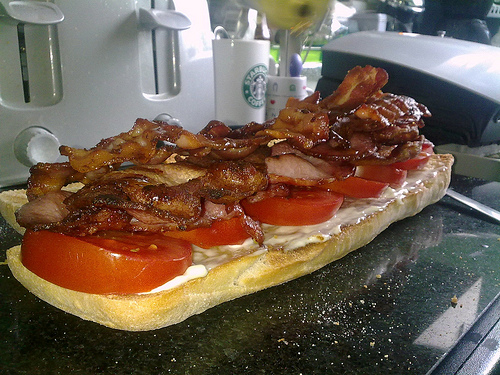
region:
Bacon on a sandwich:
[37, 138, 268, 238]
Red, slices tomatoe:
[17, 220, 221, 298]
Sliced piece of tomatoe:
[187, 210, 257, 239]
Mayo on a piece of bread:
[221, 213, 287, 256]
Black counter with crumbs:
[389, 230, 490, 295]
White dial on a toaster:
[13, 120, 77, 170]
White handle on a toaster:
[134, 9, 215, 108]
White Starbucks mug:
[217, 36, 290, 122]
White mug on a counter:
[270, 68, 337, 118]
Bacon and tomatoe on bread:
[251, 76, 496, 216]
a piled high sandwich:
[61, 78, 486, 308]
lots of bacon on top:
[55, 63, 469, 256]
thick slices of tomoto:
[66, 135, 420, 312]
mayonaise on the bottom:
[146, 160, 424, 287]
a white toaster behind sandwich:
[11, 0, 258, 178]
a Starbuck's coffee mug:
[211, 18, 289, 144]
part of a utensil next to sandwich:
[417, 165, 497, 225]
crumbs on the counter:
[297, 246, 474, 373]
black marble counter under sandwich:
[3, 176, 498, 366]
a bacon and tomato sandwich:
[25, 132, 439, 325]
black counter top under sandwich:
[1, 162, 496, 370]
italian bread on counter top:
[5, 150, 455, 335]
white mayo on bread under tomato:
[135, 260, 210, 295]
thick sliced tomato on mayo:
[15, 227, 190, 293]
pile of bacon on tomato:
[15, 65, 430, 245]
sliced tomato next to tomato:
[160, 215, 250, 247]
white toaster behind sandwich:
[0, 0, 212, 190]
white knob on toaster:
[11, 125, 58, 165]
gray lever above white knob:
[2, 0, 58, 21]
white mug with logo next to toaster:
[212, 35, 267, 121]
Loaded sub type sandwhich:
[6, 60, 454, 334]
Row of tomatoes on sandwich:
[21, 138, 438, 297]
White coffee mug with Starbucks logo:
[212, 36, 269, 125]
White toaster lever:
[131, 1, 193, 101]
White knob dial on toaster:
[11, 120, 61, 169]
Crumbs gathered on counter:
[313, 262, 498, 370]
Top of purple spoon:
[288, 50, 303, 77]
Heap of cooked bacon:
[15, 63, 432, 233]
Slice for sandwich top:
[0, 177, 83, 234]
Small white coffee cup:
[264, 74, 315, 123]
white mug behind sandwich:
[212, 36, 273, 125]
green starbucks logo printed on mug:
[242, 63, 270, 108]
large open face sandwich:
[4, 63, 461, 330]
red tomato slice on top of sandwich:
[20, 226, 192, 294]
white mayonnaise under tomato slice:
[150, 242, 251, 294]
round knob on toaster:
[16, 127, 62, 167]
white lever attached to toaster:
[3, 0, 65, 27]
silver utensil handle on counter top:
[447, 188, 498, 221]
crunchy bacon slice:
[58, 118, 184, 169]